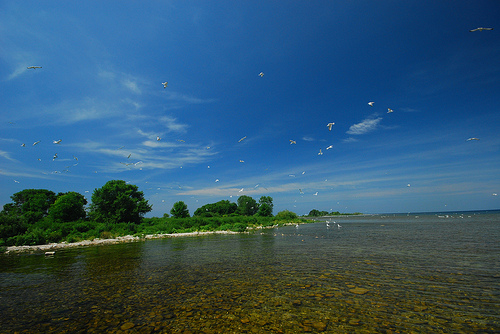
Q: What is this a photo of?
A: Beach.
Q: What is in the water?
A: Rocks.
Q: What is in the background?
A: Trees.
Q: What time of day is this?
A: Daytime.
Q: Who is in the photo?
A: No one.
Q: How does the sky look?
A: Clear.